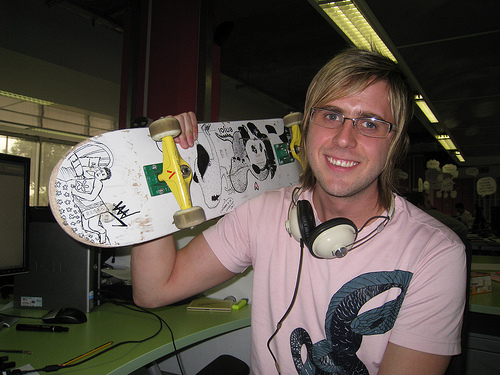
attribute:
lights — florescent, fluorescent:
[308, 2, 402, 61]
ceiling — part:
[268, 5, 499, 79]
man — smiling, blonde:
[294, 80, 441, 363]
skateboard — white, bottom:
[49, 140, 277, 226]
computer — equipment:
[1, 157, 113, 342]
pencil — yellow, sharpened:
[61, 339, 111, 366]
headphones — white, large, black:
[279, 193, 368, 259]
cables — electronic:
[9, 334, 154, 373]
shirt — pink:
[237, 228, 436, 362]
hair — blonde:
[307, 48, 404, 84]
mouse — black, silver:
[33, 302, 90, 327]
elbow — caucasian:
[128, 272, 206, 318]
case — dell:
[90, 281, 119, 304]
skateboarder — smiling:
[286, 62, 448, 267]